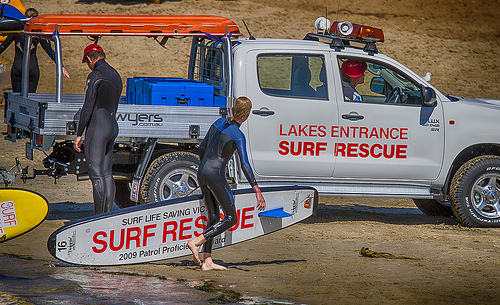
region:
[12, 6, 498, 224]
a rescue vehicle on the beach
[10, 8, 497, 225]
the vehicle is a white pickup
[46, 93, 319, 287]
a person carrying a surfboard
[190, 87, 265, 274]
the person is wet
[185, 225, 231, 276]
the person is barefoot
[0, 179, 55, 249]
the front of a yellow surfboard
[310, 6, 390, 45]
a light on top of the pickup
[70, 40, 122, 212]
a man leaning over the pickup bed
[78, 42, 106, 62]
a man wearing a baseball cap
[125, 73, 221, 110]
blue containers in the pickup bed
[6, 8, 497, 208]
The pickup truck is white.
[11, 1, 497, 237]
The truck is parked on the sand.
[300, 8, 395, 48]
Orange light on top of truck.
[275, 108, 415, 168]
The truck says lake entrance surf rescue.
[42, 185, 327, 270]
The white board says surf rescue in red text.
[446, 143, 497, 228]
A front wheel on a truck.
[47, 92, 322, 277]
The man is carrying a surfboard.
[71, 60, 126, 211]
The man is wearing a black wet suit.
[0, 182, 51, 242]
A yellow surfboard is partially visible.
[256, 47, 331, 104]
A window on the truck.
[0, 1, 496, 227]
White and red rescue truck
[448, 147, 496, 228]
Right front wheel of white recue truck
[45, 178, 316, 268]
White, red and black surfboard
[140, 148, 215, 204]
Right rear tire of recue truck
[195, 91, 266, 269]
young boy carrying surfboard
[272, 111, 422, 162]
Name of company on side of truck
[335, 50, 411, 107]
Passenger window on right side of truck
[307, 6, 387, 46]
Emergency lights on top of truck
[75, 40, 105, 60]
Red helmet on man's head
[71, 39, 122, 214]
Man standing next to truck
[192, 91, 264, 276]
A lifeguard in a wet suit.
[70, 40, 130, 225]
A man wearing a red hat.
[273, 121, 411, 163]
Red letters on side of truck.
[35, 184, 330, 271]
A blue and white surf board.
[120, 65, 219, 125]
Blue boxes on the back of the truck.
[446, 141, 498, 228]
Sand covering the tread of a tire.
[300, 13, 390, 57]
Emergency lights on top of truck.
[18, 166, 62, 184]
A black trailor hitch on truck.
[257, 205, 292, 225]
A blue fine on the surf board.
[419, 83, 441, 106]
A black mirror on the truck.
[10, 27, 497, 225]
white van in seashore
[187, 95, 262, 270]
blonde woman in wetsuit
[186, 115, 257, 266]
wetsuit is blue and black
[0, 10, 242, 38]
orange stairways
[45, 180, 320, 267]
blue and white surfboard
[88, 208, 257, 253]
surf rescue red letters in surfboard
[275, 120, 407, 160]
red letters in right side of van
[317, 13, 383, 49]
orange lights in the top of van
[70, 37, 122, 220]
manin black wetsuit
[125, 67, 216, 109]
blue boxes in the cabin